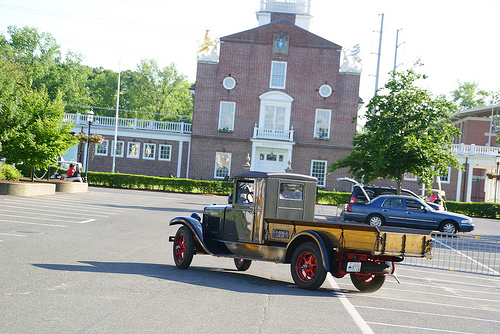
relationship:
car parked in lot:
[166, 160, 434, 296] [0, 183, 484, 332]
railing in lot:
[393, 231, 498, 276] [0, 183, 484, 332]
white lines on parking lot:
[309, 257, 499, 331] [2, 180, 496, 331]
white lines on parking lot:
[7, 197, 117, 264] [2, 180, 496, 331]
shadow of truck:
[28, 260, 333, 298] [166, 165, 436, 294]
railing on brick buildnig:
[62, 101, 192, 136] [64, 0, 499, 208]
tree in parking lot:
[0, 27, 88, 178] [41, 166, 466, 314]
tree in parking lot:
[343, 65, 464, 189] [41, 166, 466, 314]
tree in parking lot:
[4, 27, 90, 179] [41, 166, 466, 314]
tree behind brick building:
[425, 78, 495, 129] [135, 8, 405, 206]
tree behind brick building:
[113, 58, 191, 122] [135, 8, 405, 206]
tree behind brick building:
[67, 64, 117, 120] [135, 8, 405, 206]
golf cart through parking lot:
[47, 157, 82, 180] [2, 180, 496, 331]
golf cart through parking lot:
[415, 185, 445, 205] [2, 180, 496, 331]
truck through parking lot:
[166, 165, 436, 294] [2, 180, 496, 331]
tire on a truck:
[288, 241, 325, 284] [166, 165, 436, 294]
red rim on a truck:
[294, 248, 319, 281] [166, 165, 436, 294]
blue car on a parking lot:
[338, 170, 475, 234] [2, 180, 496, 331]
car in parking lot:
[331, 189, 475, 251] [2, 165, 472, 330]